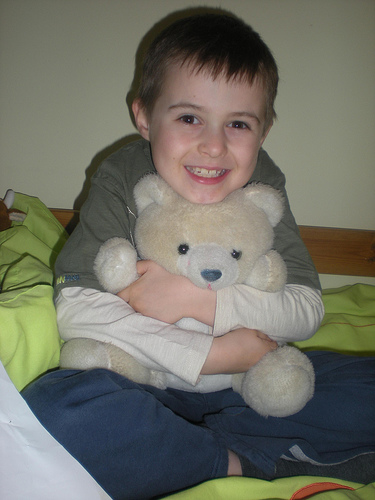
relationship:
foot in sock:
[277, 453, 373, 480] [234, 448, 373, 486]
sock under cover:
[234, 448, 373, 486] [1, 314, 363, 490]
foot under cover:
[277, 453, 373, 480] [1, 314, 363, 490]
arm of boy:
[55, 282, 273, 385] [20, 7, 374, 499]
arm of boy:
[134, 260, 326, 340] [20, 7, 374, 499]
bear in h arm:
[172, 237, 247, 270] [55, 282, 273, 385]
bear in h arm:
[172, 237, 247, 270] [134, 260, 326, 340]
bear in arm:
[60, 171, 315, 419] [55, 286, 278, 374]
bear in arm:
[60, 171, 315, 419] [38, 247, 339, 390]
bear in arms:
[60, 171, 315, 419] [51, 138, 324, 373]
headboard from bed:
[10, 0, 316, 4] [7, 219, 373, 408]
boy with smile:
[20, 7, 374, 499] [181, 158, 238, 183]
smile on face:
[181, 158, 238, 183] [154, 63, 268, 202]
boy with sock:
[20, 7, 374, 499] [231, 452, 375, 485]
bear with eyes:
[60, 171, 315, 419] [165, 235, 200, 274]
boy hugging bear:
[18, 5, 374, 500] [139, 184, 272, 309]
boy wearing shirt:
[18, 5, 374, 500] [61, 140, 136, 253]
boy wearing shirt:
[18, 5, 374, 500] [82, 153, 140, 225]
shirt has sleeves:
[82, 153, 140, 225] [213, 270, 326, 342]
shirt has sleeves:
[82, 153, 140, 225] [54, 286, 214, 386]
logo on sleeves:
[50, 265, 71, 286] [60, 156, 330, 302]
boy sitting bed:
[20, 7, 374, 499] [3, 188, 374, 497]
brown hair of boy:
[134, 5, 280, 138] [20, 7, 374, 499]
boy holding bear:
[18, 5, 374, 500] [54, 170, 312, 419]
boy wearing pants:
[18, 5, 374, 500] [19, 347, 371, 494]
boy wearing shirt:
[20, 7, 374, 499] [58, 133, 334, 304]